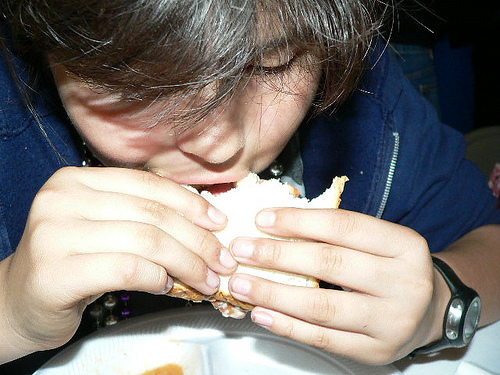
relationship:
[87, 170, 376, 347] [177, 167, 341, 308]
fingers on bread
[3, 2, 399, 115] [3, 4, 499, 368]
hair of person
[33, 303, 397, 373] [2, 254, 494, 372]
plate on table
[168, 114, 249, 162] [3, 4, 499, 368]
nose of person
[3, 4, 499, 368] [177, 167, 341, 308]
person eating bread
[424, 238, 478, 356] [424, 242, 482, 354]
watch around wrist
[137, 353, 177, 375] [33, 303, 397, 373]
stain on plate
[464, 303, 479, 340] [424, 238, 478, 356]
face of watch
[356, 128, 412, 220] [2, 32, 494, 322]
zipper on sweater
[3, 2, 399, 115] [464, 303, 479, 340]
hair in face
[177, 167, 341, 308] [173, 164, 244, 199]
bread near mouth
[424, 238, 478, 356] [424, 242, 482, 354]
watch on wrist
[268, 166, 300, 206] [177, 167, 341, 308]
meat on bread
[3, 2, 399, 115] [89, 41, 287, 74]
hair over eyes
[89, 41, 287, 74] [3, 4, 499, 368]
eyes of person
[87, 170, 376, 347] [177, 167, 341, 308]
fingers holding bread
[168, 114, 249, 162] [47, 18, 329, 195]
nose on face